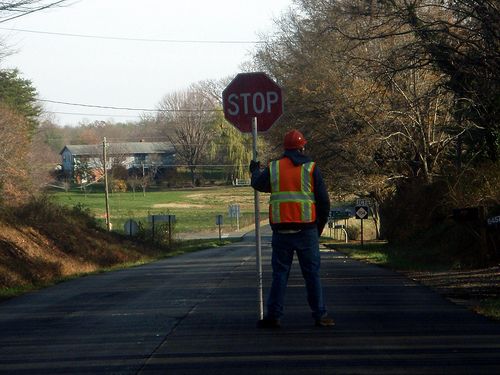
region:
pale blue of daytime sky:
[1, 1, 292, 124]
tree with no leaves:
[159, 92, 219, 183]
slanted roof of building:
[65, 140, 185, 158]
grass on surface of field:
[68, 190, 193, 230]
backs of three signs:
[123, 212, 225, 244]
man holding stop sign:
[219, 69, 335, 328]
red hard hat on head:
[280, 131, 307, 155]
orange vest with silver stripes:
[265, 157, 315, 231]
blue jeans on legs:
[264, 227, 326, 321]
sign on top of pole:
[353, 196, 371, 245]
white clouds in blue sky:
[60, 7, 120, 40]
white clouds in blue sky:
[162, 7, 241, 49]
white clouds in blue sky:
[72, 45, 135, 89]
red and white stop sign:
[226, 71, 277, 131]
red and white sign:
[223, 68, 283, 134]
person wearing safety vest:
[253, 160, 319, 243]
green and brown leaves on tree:
[7, 127, 39, 171]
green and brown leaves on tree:
[332, 41, 381, 104]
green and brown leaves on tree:
[347, 84, 413, 141]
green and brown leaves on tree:
[388, 80, 473, 150]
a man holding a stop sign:
[213, 65, 360, 326]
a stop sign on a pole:
[219, 65, 287, 225]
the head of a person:
[274, 125, 314, 165]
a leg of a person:
[299, 248, 330, 328]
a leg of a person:
[264, 245, 293, 329]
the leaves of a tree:
[336, 72, 362, 129]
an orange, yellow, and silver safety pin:
[261, 150, 325, 232]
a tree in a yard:
[152, 87, 213, 196]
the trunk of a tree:
[188, 147, 200, 188]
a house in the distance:
[64, 130, 186, 198]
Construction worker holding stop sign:
[216, 56, 333, 344]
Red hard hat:
[277, 126, 310, 151]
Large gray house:
[58, 134, 184, 192]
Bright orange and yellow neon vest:
[270, 154, 323, 231]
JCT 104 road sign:
[348, 189, 378, 254]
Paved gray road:
[11, 183, 471, 373]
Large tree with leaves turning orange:
[255, 0, 491, 290]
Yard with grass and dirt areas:
[77, 184, 259, 229]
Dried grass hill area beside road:
[1, 205, 157, 293]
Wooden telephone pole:
[95, 130, 116, 235]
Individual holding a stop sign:
[218, 65, 360, 328]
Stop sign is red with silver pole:
[220, 68, 285, 339]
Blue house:
[60, 128, 192, 197]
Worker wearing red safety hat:
[241, 126, 345, 331]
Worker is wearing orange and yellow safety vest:
[246, 125, 342, 330]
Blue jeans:
[248, 130, 328, 322]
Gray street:
[144, 260, 246, 357]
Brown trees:
[331, 19, 498, 300]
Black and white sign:
[348, 196, 377, 246]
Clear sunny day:
[75, 42, 151, 97]